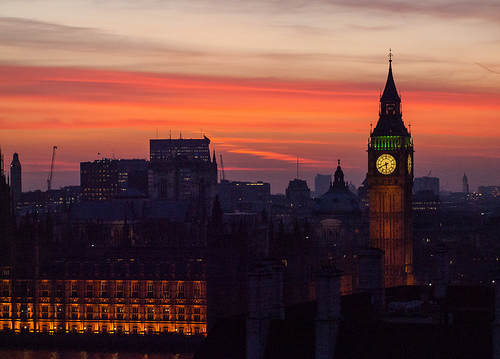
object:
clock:
[406, 153, 414, 174]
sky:
[2, 0, 500, 169]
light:
[0, 273, 212, 338]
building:
[2, 185, 242, 339]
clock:
[374, 153, 397, 174]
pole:
[290, 152, 302, 174]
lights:
[368, 127, 414, 153]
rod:
[379, 47, 399, 79]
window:
[2, 281, 11, 294]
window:
[113, 283, 128, 297]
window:
[141, 323, 154, 336]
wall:
[0, 254, 226, 354]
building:
[2, 49, 499, 356]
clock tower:
[360, 46, 417, 287]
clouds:
[344, 18, 400, 40]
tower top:
[382, 47, 396, 82]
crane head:
[35, 130, 64, 203]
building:
[77, 151, 152, 202]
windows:
[0, 323, 15, 336]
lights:
[67, 138, 140, 215]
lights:
[242, 172, 282, 199]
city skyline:
[0, 80, 499, 236]